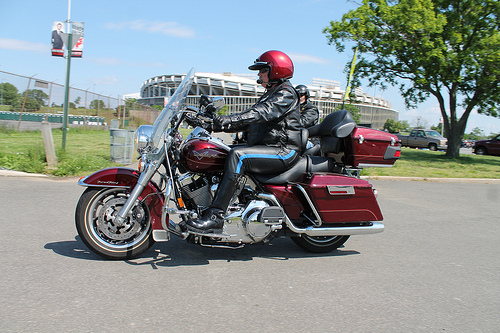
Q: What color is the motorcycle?
A: Red and chrome.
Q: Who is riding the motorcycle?
A: A man.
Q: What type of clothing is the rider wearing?
A: Black leather.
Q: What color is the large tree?
A: Green.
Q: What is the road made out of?
A: Concrete.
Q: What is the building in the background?
A: A stadium.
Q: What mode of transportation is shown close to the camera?
A: Motorcycle.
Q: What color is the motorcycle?
A: Red.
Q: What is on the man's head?
A: Helmet.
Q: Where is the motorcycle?
A: Road.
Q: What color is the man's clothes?
A: Black.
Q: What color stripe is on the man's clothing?
A: Blue.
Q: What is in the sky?
A: Clouds.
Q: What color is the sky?
A: Blue.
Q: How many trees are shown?
A: 1.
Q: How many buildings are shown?
A: 1.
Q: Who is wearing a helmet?
A: Motorbike rider.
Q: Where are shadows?
A: On the ground.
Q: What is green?
A: Grass.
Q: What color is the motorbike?
A: Red.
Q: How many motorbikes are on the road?
A: Two.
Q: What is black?
A: Rider's boots.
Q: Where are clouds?
A: In the sky.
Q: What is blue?
A: Sky.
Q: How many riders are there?
A: 2.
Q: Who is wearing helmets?
A: Both riders.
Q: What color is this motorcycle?
A: Red.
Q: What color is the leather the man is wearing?
A: Black.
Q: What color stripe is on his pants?
A: Blue.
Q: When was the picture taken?
A: The daytime.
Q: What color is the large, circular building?
A: White.